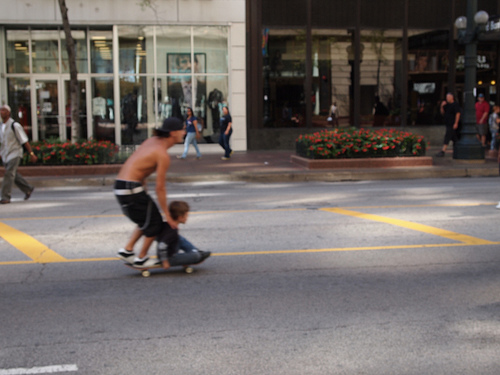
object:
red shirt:
[475, 100, 490, 126]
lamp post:
[454, 0, 489, 163]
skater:
[115, 116, 187, 268]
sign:
[93, 96, 109, 117]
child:
[157, 200, 211, 265]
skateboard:
[130, 261, 203, 279]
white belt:
[113, 185, 148, 199]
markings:
[317, 204, 499, 267]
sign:
[38, 100, 52, 113]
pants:
[112, 179, 175, 239]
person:
[474, 94, 490, 152]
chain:
[139, 199, 155, 233]